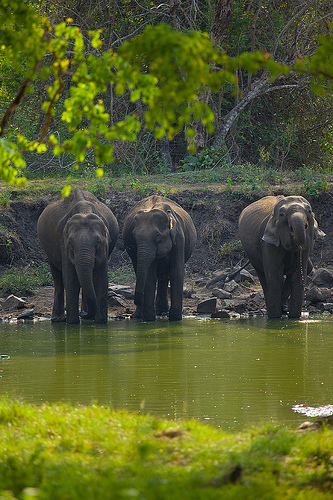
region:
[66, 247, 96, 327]
The trunk of the elephant on the left.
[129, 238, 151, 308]
The trunk of the elephant in the middle.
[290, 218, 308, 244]
The trunk of the elephant on the right.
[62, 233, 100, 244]
The eyes of the elephant on the left.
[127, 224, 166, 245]
The eyes of the elephant in the middle.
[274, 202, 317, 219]
The eyes of the elephant on the right.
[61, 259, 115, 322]
The front legs of the elephant on the left.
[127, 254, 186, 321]
The front legs of the elephant in the middle.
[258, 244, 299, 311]
The front legs of the elephant on the right.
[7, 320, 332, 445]
The water in front of the elephants.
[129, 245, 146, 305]
trunk on the elephant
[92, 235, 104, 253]
an eye on the elephant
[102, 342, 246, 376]
green water in pond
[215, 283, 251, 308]
several gray rocks by pond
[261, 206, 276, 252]
portion of elephant's ear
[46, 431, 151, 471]
patch of green grass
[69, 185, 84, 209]
part of the elephant's back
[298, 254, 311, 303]
water coming from trunk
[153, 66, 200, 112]
leaves on tree branches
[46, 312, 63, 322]
back foot of elephant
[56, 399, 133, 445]
sunlight shining on the grass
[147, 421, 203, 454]
patch of mud poking through the grass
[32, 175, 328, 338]
trio of elephants on the riverbank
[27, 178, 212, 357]
elephants getting a drink of water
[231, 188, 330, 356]
elephant drinking water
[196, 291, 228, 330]
rocks on the riverbank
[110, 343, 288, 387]
sun shining at the water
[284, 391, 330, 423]
ripples in the river water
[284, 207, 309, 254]
trunk drinking water from the river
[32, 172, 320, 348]
elephants walking into the water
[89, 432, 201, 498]
The grass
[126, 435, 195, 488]
The grass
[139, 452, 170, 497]
The grass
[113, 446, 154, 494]
The grass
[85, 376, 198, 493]
The grass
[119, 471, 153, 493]
The grass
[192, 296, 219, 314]
Rock on a shore line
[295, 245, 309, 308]
Water dripping from an elephant's mouth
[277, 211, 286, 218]
Black eye of an elephant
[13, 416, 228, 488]
Green grass on a shoreline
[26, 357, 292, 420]
Calm water in a river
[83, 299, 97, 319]
Wet trunk of an elephant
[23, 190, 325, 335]
Three elephants at a water's edge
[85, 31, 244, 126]
Green leaves on a tree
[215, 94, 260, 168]
Tree trunk in a forest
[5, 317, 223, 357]
Shadows in a river